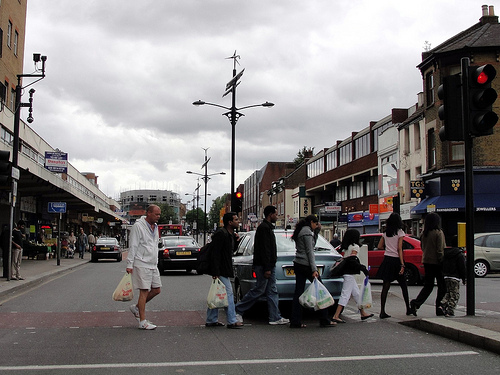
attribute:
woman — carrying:
[291, 207, 325, 324]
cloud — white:
[19, 88, 309, 170]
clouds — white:
[108, 57, 334, 136]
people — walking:
[200, 205, 487, 317]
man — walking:
[114, 200, 161, 329]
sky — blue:
[78, 30, 159, 131]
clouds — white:
[122, 29, 148, 70]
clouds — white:
[186, 38, 397, 115]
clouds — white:
[19, 4, 499, 210]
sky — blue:
[18, 0, 499, 207]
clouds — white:
[93, 37, 348, 131]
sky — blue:
[25, 1, 498, 185]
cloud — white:
[68, 2, 301, 45]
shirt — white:
[119, 215, 166, 273]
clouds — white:
[148, 107, 190, 147]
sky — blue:
[123, 42, 184, 81]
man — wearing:
[62, 177, 198, 347]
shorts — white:
[126, 260, 175, 302]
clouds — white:
[295, 29, 364, 90]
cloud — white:
[34, 20, 369, 152]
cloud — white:
[291, 39, 431, 113]